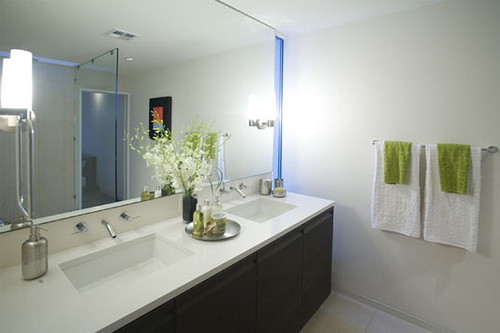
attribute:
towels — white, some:
[377, 130, 470, 257]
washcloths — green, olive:
[368, 121, 475, 204]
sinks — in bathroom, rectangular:
[63, 194, 291, 304]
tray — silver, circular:
[169, 199, 247, 257]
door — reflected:
[61, 79, 122, 212]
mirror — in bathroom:
[6, 14, 289, 185]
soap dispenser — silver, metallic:
[24, 244, 52, 283]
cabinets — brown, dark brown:
[111, 216, 352, 327]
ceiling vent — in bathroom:
[102, 25, 138, 50]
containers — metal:
[256, 170, 288, 205]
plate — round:
[184, 216, 265, 260]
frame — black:
[123, 94, 175, 151]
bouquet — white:
[142, 130, 226, 198]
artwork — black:
[148, 95, 174, 149]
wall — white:
[126, 62, 271, 165]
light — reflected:
[3, 36, 34, 125]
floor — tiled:
[318, 282, 430, 332]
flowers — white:
[126, 124, 229, 194]